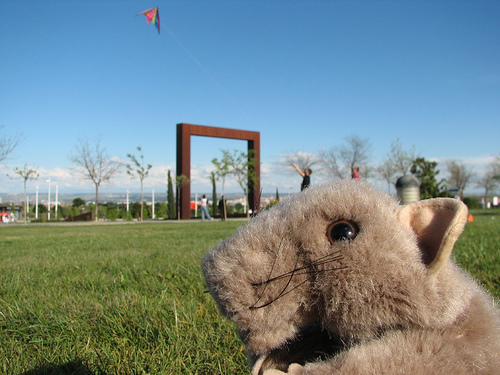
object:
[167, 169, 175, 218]
tree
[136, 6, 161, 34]
kite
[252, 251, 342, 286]
whisker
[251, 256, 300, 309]
whisker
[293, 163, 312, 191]
man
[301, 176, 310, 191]
top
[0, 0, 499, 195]
sky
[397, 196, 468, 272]
ear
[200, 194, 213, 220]
person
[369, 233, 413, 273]
color gray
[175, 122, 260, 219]
frame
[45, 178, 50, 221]
post light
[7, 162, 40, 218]
tree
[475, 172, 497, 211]
tree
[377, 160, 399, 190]
tree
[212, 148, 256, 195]
tree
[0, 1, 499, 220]
background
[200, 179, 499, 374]
animal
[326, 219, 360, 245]
eye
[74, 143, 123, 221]
bare trees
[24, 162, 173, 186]
cloud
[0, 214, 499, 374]
grass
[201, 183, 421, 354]
mouse's face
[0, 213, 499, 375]
field